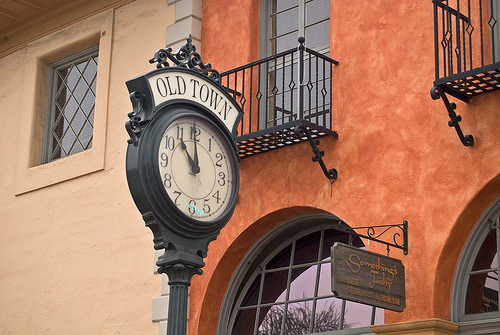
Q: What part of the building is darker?
A: The orange section.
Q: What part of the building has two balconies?
A: The orange section.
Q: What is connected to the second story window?
A: A balcony.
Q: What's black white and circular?
A: Clock.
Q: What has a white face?
A: The clock.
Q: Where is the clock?
A: Metal pole.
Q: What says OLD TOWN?
A: The sign.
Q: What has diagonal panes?
A: The windows.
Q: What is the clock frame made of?
A: Metal.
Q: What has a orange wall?
A: The building.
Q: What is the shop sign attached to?
A: The building.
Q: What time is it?
A: 11:00.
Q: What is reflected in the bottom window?
A: A tree.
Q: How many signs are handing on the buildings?
A: One.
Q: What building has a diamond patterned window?
A: The one on the left.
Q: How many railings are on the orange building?
A: Two.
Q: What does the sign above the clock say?
A: Old Town.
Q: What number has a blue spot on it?
A: 6.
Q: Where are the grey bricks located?
A: Between the buildings.